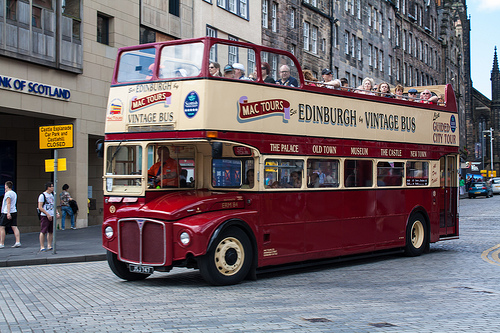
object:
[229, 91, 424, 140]
words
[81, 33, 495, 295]
bus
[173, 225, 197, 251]
lights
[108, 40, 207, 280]
front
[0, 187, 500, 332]
street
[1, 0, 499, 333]
city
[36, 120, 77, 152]
sign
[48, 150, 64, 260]
pole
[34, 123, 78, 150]
letters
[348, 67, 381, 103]
people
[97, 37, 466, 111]
top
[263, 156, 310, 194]
windows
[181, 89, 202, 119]
decal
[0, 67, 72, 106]
words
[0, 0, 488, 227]
buildings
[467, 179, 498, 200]
car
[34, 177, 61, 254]
man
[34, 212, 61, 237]
shorts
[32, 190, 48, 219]
backpack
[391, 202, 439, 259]
tires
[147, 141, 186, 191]
bus driver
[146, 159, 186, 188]
shirt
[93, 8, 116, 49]
window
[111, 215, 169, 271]
grate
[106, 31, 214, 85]
window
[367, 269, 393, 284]
tiles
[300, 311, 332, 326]
spot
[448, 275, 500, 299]
drain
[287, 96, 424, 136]
lettering